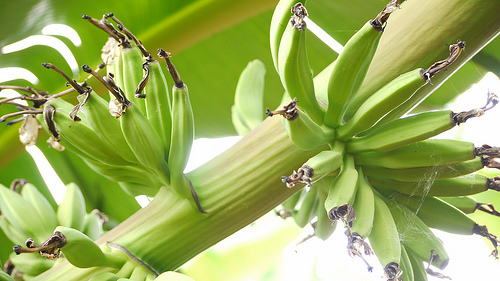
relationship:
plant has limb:
[5, 1, 498, 275] [22, 2, 498, 279]